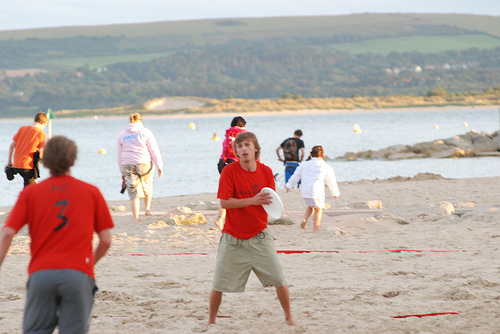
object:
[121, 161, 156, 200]
shorts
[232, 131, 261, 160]
hair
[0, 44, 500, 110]
trees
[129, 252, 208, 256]
line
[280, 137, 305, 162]
black shirt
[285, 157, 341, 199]
white jacket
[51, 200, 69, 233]
number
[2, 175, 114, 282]
shirt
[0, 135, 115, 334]
man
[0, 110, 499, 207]
water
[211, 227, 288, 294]
shorts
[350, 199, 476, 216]
pebbles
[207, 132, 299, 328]
man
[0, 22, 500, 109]
forest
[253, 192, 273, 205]
hand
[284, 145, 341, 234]
girl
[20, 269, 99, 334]
shorts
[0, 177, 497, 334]
sand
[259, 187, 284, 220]
frisbee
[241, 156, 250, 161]
chin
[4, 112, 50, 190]
man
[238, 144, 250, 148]
eyes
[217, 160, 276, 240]
shirt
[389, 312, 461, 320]
line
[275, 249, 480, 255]
line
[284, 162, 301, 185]
shorts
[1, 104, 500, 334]
beach